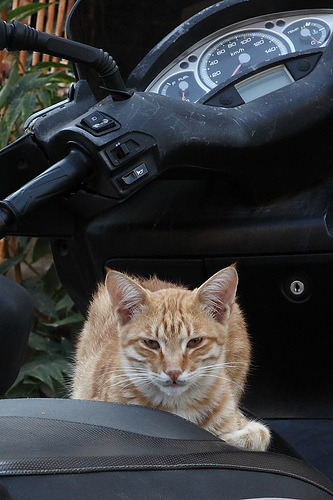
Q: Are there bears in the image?
A: No, there are no bears.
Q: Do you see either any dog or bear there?
A: No, there are no bears or dogs.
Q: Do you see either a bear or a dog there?
A: No, there are no bears or dogs.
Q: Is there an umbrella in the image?
A: No, there are no umbrellas.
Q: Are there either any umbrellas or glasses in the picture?
A: No, there are no umbrellas or glasses.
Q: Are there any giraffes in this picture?
A: No, there are no giraffes.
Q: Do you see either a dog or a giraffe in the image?
A: No, there are no giraffes or dogs.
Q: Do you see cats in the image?
A: Yes, there is a cat.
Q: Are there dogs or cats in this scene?
A: Yes, there is a cat.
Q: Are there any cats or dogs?
A: Yes, there is a cat.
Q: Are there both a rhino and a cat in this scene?
A: No, there is a cat but no rhinos.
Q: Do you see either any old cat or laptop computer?
A: Yes, there is an old cat.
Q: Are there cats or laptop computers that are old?
A: Yes, the cat is old.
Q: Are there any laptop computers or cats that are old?
A: Yes, the cat is old.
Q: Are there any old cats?
A: Yes, there is an old cat.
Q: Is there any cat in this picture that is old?
A: Yes, there is a cat that is old.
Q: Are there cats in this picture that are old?
A: Yes, there is a cat that is old.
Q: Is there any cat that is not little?
A: Yes, there is a old cat.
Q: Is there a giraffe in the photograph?
A: No, there are no giraffes.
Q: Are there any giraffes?
A: No, there are no giraffes.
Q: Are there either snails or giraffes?
A: No, there are no giraffes or snails.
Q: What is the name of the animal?
A: The animal is a cat.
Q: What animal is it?
A: The animal is a cat.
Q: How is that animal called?
A: This is a cat.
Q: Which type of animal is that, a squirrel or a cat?
A: This is a cat.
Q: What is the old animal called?
A: The animal is a cat.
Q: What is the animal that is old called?
A: The animal is a cat.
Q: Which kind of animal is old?
A: The animal is a cat.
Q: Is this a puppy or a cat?
A: This is a cat.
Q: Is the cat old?
A: Yes, the cat is old.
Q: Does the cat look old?
A: Yes, the cat is old.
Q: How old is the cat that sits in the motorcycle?
A: The cat is old.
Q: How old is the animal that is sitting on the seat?
A: The cat is old.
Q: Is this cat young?
A: No, the cat is old.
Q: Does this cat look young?
A: No, the cat is old.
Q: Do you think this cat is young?
A: No, the cat is old.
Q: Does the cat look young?
A: No, the cat is old.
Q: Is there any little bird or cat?
A: No, there is a cat but it is old.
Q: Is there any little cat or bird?
A: No, there is a cat but it is old.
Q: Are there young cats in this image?
A: No, there is a cat but it is old.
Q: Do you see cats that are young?
A: No, there is a cat but it is old.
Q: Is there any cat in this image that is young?
A: No, there is a cat but it is old.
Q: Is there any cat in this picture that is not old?
A: No, there is a cat but it is old.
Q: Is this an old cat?
A: Yes, this is an old cat.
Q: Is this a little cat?
A: No, this is an old cat.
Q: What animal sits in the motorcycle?
A: The cat sits in the motorcycle.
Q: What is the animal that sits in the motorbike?
A: The animal is a cat.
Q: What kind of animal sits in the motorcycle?
A: The animal is a cat.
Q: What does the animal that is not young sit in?
A: The cat sits in the motorcycle.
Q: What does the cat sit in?
A: The cat sits in the motorcycle.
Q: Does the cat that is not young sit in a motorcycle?
A: Yes, the cat sits in a motorcycle.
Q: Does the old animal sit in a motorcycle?
A: Yes, the cat sits in a motorcycle.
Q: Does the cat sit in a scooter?
A: No, the cat sits in a motorcycle.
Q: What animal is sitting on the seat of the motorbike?
A: The cat is sitting on the seat.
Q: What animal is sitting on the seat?
A: The cat is sitting on the seat.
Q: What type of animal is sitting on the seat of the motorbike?
A: The animal is a cat.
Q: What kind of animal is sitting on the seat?
A: The animal is a cat.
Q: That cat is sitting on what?
A: The cat is sitting on the seat.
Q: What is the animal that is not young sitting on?
A: The cat is sitting on the seat.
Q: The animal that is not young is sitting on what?
A: The cat is sitting on the seat.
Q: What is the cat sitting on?
A: The cat is sitting on the seat.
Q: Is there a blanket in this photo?
A: No, there are no blankets.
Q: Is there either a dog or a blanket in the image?
A: No, there are no blankets or dogs.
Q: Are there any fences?
A: No, there are no fences.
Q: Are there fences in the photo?
A: No, there are no fences.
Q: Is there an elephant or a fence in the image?
A: No, there are no fences or elephants.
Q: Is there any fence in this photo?
A: No, there are no fences.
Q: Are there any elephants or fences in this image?
A: No, there are no fences or elephants.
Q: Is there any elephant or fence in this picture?
A: No, there are no fences or elephants.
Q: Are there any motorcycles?
A: Yes, there is a motorcycle.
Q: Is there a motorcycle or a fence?
A: Yes, there is a motorcycle.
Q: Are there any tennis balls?
A: No, there are no tennis balls.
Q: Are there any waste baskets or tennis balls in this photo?
A: No, there are no tennis balls or waste baskets.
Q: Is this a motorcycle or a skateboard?
A: This is a motorcycle.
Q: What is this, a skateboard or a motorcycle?
A: This is a motorcycle.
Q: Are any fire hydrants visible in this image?
A: No, there are no fire hydrants.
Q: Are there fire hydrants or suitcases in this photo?
A: No, there are no fire hydrants or suitcases.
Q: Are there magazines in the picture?
A: No, there are no magazines.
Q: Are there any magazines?
A: No, there are no magazines.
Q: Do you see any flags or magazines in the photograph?
A: No, there are no magazines or flags.